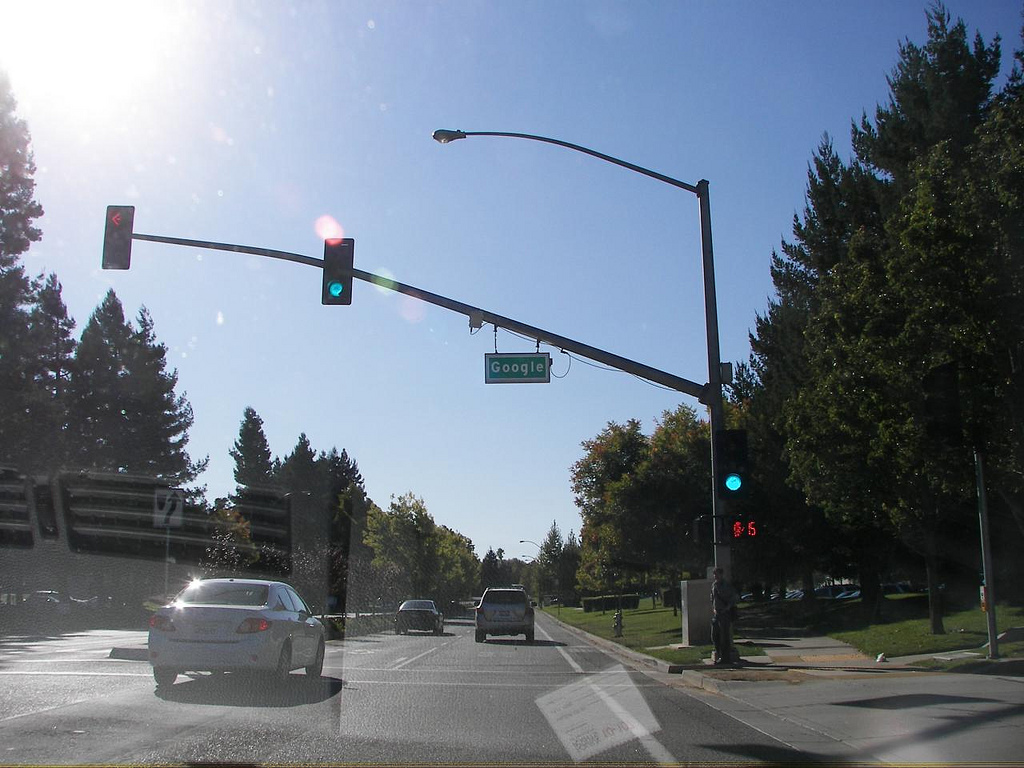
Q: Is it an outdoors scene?
A: Yes, it is outdoors.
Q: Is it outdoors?
A: Yes, it is outdoors.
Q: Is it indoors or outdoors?
A: It is outdoors.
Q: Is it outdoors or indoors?
A: It is outdoors.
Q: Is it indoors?
A: No, it is outdoors.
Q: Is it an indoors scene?
A: No, it is outdoors.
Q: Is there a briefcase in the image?
A: No, there are no briefcases.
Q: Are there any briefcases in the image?
A: No, there are no briefcases.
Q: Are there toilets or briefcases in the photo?
A: No, there are no briefcases or toilets.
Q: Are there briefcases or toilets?
A: No, there are no briefcases or toilets.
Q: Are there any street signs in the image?
A: Yes, there is a street sign.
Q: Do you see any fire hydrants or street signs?
A: Yes, there is a street sign.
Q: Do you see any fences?
A: No, there are no fences.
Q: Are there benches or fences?
A: No, there are no fences or benches.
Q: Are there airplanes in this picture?
A: No, there are no airplanes.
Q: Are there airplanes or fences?
A: No, there are no airplanes or fences.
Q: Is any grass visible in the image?
A: Yes, there is grass.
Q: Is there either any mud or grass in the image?
A: Yes, there is grass.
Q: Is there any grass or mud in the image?
A: Yes, there is grass.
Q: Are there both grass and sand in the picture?
A: No, there is grass but no sand.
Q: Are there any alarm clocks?
A: No, there are no alarm clocks.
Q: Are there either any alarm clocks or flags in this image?
A: No, there are no alarm clocks or flags.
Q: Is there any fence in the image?
A: No, there are no fences.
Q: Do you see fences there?
A: No, there are no fences.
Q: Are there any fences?
A: No, there are no fences.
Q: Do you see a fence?
A: No, there are no fences.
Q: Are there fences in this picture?
A: No, there are no fences.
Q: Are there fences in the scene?
A: No, there are no fences.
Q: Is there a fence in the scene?
A: No, there are no fences.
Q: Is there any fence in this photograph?
A: No, there are no fences.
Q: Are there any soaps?
A: No, there are no soaps.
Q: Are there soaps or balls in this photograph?
A: No, there are no soaps or balls.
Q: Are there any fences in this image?
A: No, there are no fences.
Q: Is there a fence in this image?
A: No, there are no fences.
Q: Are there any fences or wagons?
A: No, there are no fences or wagons.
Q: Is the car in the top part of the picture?
A: No, the car is in the bottom of the image.